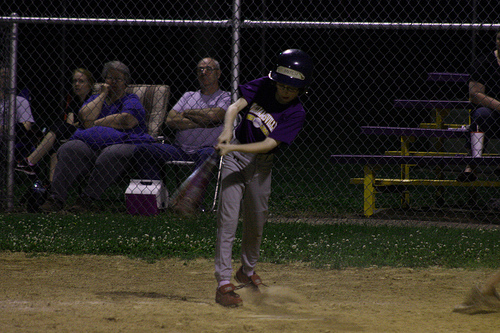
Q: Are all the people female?
A: No, they are both male and female.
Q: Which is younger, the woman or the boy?
A: The boy is younger than the woman.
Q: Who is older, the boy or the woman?
A: The woman is older than the boy.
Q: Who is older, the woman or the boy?
A: The woman is older than the boy.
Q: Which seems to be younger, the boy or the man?
A: The boy is younger than the man.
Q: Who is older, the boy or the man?
A: The man is older than the boy.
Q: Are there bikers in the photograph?
A: No, there are no bikers.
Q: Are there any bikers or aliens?
A: No, there are no bikers or aliens.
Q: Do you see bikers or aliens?
A: No, there are no bikers or aliens.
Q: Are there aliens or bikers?
A: No, there are no bikers or aliens.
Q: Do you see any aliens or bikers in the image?
A: No, there are no bikers or aliens.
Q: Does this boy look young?
A: Yes, the boy is young.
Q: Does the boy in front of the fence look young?
A: Yes, the boy is young.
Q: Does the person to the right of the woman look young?
A: Yes, the boy is young.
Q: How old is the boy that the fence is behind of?
A: The boy is young.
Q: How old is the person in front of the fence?
A: The boy is young.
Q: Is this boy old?
A: No, the boy is young.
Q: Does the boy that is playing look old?
A: No, the boy is young.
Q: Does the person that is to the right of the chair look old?
A: No, the boy is young.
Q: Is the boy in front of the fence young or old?
A: The boy is young.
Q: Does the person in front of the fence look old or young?
A: The boy is young.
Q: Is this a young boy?
A: Yes, this is a young boy.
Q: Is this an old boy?
A: No, this is a young boy.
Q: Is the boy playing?
A: Yes, the boy is playing.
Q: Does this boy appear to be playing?
A: Yes, the boy is playing.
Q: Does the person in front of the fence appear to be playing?
A: Yes, the boy is playing.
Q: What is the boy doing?
A: The boy is playing.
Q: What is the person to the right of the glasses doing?
A: The boy is playing.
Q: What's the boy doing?
A: The boy is playing.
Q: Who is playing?
A: The boy is playing.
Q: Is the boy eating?
A: No, the boy is playing.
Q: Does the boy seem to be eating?
A: No, the boy is playing.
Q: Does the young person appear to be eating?
A: No, the boy is playing.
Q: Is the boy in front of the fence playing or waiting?
A: The boy is playing.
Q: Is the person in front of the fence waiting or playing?
A: The boy is playing.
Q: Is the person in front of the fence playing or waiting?
A: The boy is playing.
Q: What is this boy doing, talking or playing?
A: The boy is playing.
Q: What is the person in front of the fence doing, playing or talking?
A: The boy is playing.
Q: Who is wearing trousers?
A: The boy is wearing trousers.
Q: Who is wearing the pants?
A: The boy is wearing trousers.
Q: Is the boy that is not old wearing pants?
A: Yes, the boy is wearing pants.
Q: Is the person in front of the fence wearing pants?
A: Yes, the boy is wearing pants.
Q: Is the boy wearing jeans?
A: No, the boy is wearing pants.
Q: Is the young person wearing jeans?
A: No, the boy is wearing pants.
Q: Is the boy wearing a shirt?
A: Yes, the boy is wearing a shirt.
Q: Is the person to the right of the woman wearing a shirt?
A: Yes, the boy is wearing a shirt.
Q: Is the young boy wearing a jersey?
A: No, the boy is wearing a shirt.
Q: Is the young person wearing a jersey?
A: No, the boy is wearing a shirt.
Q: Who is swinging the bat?
A: The boy is swinging the bat.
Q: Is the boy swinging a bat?
A: Yes, the boy is swinging a bat.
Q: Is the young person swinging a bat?
A: Yes, the boy is swinging a bat.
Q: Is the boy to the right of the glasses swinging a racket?
A: No, the boy is swinging a bat.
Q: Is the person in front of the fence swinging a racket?
A: No, the boy is swinging a bat.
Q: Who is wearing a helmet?
A: The boy is wearing a helmet.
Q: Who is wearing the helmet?
A: The boy is wearing a helmet.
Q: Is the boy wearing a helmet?
A: Yes, the boy is wearing a helmet.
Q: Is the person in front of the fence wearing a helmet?
A: Yes, the boy is wearing a helmet.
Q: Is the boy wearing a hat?
A: No, the boy is wearing a helmet.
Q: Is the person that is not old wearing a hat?
A: No, the boy is wearing a helmet.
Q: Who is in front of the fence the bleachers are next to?
A: The boy is in front of the fence.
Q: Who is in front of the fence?
A: The boy is in front of the fence.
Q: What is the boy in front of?
A: The boy is in front of the fence.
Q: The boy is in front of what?
A: The boy is in front of the fence.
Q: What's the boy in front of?
A: The boy is in front of the fence.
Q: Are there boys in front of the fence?
A: Yes, there is a boy in front of the fence.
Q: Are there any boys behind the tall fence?
A: No, the boy is in front of the fence.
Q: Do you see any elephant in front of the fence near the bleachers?
A: No, there is a boy in front of the fence.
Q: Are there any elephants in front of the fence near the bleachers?
A: No, there is a boy in front of the fence.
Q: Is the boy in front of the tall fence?
A: Yes, the boy is in front of the fence.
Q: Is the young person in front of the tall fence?
A: Yes, the boy is in front of the fence.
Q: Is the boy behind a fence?
A: No, the boy is in front of a fence.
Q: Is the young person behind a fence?
A: No, the boy is in front of a fence.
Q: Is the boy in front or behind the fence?
A: The boy is in front of the fence.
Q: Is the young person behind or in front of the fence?
A: The boy is in front of the fence.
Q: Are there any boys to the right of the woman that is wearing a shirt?
A: Yes, there is a boy to the right of the woman.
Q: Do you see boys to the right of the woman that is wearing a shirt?
A: Yes, there is a boy to the right of the woman.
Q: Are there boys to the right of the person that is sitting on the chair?
A: Yes, there is a boy to the right of the woman.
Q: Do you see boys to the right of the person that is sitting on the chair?
A: Yes, there is a boy to the right of the woman.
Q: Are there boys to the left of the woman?
A: No, the boy is to the right of the woman.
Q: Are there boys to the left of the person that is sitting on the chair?
A: No, the boy is to the right of the woman.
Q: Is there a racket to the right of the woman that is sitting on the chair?
A: No, there is a boy to the right of the woman.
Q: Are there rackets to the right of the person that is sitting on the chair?
A: No, there is a boy to the right of the woman.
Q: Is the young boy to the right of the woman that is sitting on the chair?
A: Yes, the boy is to the right of the woman.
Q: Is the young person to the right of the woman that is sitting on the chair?
A: Yes, the boy is to the right of the woman.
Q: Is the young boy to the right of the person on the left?
A: Yes, the boy is to the right of the woman.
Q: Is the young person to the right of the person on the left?
A: Yes, the boy is to the right of the woman.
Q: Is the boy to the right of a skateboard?
A: No, the boy is to the right of the woman.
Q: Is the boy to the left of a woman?
A: No, the boy is to the right of a woman.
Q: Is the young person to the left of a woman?
A: No, the boy is to the right of a woman.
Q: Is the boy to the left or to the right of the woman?
A: The boy is to the right of the woman.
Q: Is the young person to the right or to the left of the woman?
A: The boy is to the right of the woman.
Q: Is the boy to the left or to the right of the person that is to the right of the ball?
A: The boy is to the right of the woman.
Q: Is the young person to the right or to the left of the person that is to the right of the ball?
A: The boy is to the right of the woman.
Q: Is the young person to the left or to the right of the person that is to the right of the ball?
A: The boy is to the right of the woman.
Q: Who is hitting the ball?
A: The boy is hitting the ball.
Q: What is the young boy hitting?
A: The boy is hitting the ball.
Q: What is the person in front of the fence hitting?
A: The boy is hitting the ball.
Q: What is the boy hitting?
A: The boy is hitting the ball.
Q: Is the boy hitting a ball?
A: Yes, the boy is hitting a ball.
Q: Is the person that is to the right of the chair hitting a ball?
A: Yes, the boy is hitting a ball.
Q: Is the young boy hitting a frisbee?
A: No, the boy is hitting a ball.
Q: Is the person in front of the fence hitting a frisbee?
A: No, the boy is hitting a ball.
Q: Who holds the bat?
A: The boy holds the bat.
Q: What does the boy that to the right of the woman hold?
A: The boy holds the bat.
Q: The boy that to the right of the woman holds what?
A: The boy holds the bat.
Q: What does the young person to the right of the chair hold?
A: The boy holds the bat.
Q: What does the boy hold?
A: The boy holds the bat.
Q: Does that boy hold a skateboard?
A: No, the boy holds the bat.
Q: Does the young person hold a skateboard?
A: No, the boy holds the bat.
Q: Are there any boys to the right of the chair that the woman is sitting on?
A: Yes, there is a boy to the right of the chair.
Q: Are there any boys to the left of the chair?
A: No, the boy is to the right of the chair.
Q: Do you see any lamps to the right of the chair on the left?
A: No, there is a boy to the right of the chair.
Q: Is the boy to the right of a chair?
A: Yes, the boy is to the right of a chair.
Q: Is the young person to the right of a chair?
A: Yes, the boy is to the right of a chair.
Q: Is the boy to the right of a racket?
A: No, the boy is to the right of a chair.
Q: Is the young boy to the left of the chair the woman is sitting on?
A: No, the boy is to the right of the chair.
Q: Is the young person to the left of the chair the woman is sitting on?
A: No, the boy is to the right of the chair.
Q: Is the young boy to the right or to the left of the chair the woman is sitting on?
A: The boy is to the right of the chair.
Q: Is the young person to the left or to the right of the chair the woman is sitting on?
A: The boy is to the right of the chair.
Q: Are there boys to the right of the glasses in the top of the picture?
A: Yes, there is a boy to the right of the glasses.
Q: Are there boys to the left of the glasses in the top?
A: No, the boy is to the right of the glasses.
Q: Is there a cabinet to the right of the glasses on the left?
A: No, there is a boy to the right of the glasses.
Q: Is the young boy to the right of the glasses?
A: Yes, the boy is to the right of the glasses.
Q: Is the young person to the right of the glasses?
A: Yes, the boy is to the right of the glasses.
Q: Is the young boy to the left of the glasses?
A: No, the boy is to the right of the glasses.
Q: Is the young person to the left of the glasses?
A: No, the boy is to the right of the glasses.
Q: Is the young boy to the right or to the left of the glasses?
A: The boy is to the right of the glasses.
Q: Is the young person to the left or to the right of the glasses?
A: The boy is to the right of the glasses.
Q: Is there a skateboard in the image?
A: No, there are no skateboards.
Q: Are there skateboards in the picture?
A: No, there are no skateboards.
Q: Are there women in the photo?
A: Yes, there is a woman.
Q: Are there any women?
A: Yes, there is a woman.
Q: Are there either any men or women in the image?
A: Yes, there is a woman.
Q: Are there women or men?
A: Yes, there is a woman.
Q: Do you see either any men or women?
A: Yes, there is a woman.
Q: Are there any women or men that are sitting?
A: Yes, the woman is sitting.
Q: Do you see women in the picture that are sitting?
A: Yes, there is a woman that is sitting.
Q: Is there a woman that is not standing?
A: Yes, there is a woman that is sitting.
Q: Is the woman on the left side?
A: Yes, the woman is on the left of the image.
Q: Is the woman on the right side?
A: No, the woman is on the left of the image.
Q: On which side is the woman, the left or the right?
A: The woman is on the left of the image.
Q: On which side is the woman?
A: The woman is on the left of the image.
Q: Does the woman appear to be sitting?
A: Yes, the woman is sitting.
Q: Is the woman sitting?
A: Yes, the woman is sitting.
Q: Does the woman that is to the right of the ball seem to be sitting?
A: Yes, the woman is sitting.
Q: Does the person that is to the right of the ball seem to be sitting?
A: Yes, the woman is sitting.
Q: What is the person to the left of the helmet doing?
A: The woman is sitting.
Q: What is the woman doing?
A: The woman is sitting.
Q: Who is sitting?
A: The woman is sitting.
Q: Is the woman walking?
A: No, the woman is sitting.